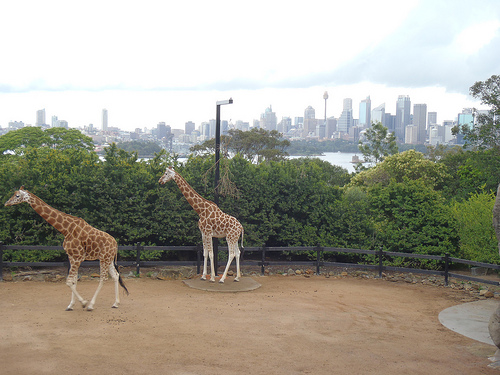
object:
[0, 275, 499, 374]
dirt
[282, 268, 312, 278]
rock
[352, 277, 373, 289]
ground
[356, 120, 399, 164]
tree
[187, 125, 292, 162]
tree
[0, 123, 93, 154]
tree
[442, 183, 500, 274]
trees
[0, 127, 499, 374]
zoo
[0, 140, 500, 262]
tree grove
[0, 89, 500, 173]
cityscape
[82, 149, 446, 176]
water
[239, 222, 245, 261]
tail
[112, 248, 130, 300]
tail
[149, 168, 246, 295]
fence giraffes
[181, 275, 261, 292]
circle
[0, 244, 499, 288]
fence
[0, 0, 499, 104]
sky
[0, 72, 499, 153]
skyline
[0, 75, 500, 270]
bushes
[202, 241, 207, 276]
leg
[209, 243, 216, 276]
leg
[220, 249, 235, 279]
leg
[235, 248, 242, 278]
leg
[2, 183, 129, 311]
giraffe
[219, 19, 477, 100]
cloud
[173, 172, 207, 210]
neck